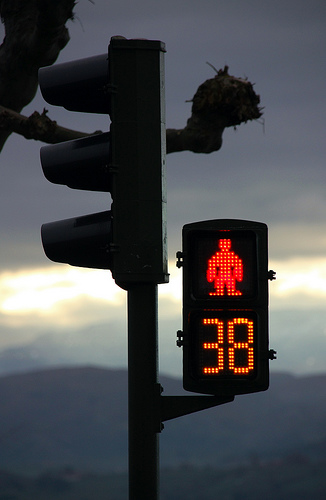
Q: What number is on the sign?
A: 38.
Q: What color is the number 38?
A: Yellow.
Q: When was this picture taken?
A: Evening.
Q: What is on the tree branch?
A: Bird's nest.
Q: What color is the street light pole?
A: Black.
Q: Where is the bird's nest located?
A: Tree branch.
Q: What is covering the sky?
A: Clouds.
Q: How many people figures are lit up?
A: 1.